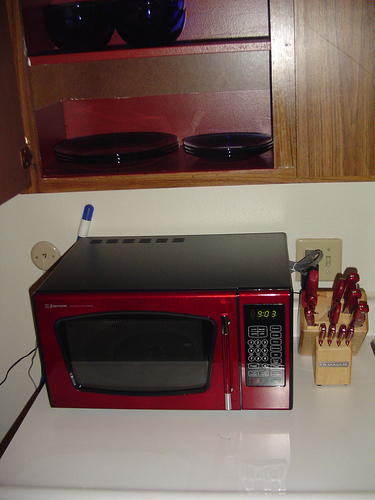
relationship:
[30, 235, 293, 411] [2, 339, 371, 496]
microwave on counter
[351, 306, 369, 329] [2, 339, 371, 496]
handle of knife on counter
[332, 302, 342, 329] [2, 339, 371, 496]
handle of knife on counter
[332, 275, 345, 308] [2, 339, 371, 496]
handle of knife on counter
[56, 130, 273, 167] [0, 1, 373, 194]
plates in cabinet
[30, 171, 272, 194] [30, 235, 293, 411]
shelf above microwave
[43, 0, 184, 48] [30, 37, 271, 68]
dishes on shelf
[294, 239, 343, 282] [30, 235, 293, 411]
light switch left of microwave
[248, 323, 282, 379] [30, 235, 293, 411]
control panel on microwave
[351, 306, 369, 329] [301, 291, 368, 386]
handle of knife in knife holder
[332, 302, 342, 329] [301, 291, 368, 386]
handle of knife in knife holder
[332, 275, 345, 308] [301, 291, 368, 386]
handle of knife in knife holder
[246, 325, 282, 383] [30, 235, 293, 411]
buttons on microwave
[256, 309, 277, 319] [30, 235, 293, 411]
9:03 readout on microwave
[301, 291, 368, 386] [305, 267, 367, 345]
knife holder with knives